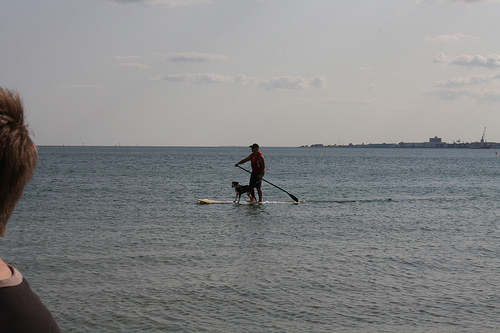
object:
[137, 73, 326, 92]
clouds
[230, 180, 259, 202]
dog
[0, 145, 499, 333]
beach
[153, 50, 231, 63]
cloud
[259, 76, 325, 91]
cloud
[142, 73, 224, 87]
cloud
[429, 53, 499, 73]
cloud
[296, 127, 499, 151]
city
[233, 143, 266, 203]
person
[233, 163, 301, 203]
paddle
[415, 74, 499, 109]
cloud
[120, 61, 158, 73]
cloud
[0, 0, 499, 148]
sky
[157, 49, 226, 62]
cloud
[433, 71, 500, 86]
cloud